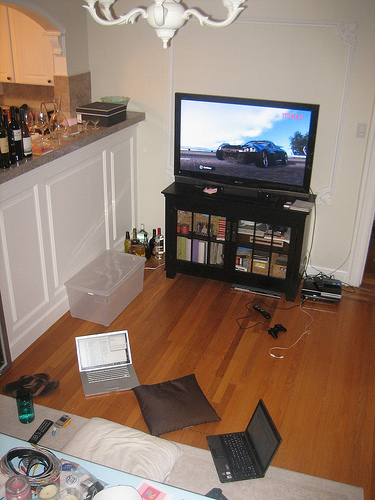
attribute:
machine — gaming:
[230, 272, 350, 371]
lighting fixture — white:
[76, 0, 251, 49]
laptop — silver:
[74, 329, 140, 397]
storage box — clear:
[61, 263, 134, 325]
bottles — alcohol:
[125, 223, 165, 261]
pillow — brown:
[129, 376, 227, 444]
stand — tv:
[161, 178, 317, 304]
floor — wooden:
[0, 239, 373, 498]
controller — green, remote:
[13, 388, 38, 429]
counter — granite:
[0, 108, 147, 180]